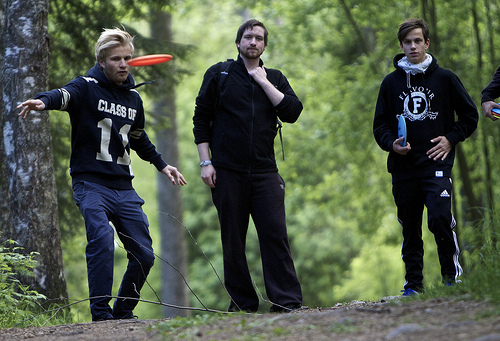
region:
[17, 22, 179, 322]
Just made frisbee airborn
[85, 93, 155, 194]
Navy shirt Class of 11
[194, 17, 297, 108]
Left hand holding collar open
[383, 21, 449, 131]
Dark blue Hoodie F bullseye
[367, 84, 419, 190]
Blue frisbee ready play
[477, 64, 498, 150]
Tip of another blue frisbee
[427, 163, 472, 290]
Pant leg white double stripe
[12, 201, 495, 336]
All standing sandy hill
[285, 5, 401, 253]
Forest behind frisbee players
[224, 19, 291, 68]
Only man facial hair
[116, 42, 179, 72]
An orange Frisbee in mid air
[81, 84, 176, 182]
Class of '11 sweat shirt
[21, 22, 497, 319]
Men playing frisbee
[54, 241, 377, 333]
A downed tree branch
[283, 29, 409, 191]
Greenery in the background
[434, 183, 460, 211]
An adidas logo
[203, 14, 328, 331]
An all black outfit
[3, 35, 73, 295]
A part of a tree trunk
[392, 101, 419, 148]
A blue frisbee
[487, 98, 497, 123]
Stack of different frisbees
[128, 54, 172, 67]
Orange frisbee in midair.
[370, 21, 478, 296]
Young man standing in forest.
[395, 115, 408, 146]
Bright blue frisbee in boy's hand.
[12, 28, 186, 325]
Young man tossing frisbee.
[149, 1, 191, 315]
Tall strong trunk of tree.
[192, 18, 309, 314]
Man with watch and backpack in forest.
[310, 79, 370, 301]
Section of green leafy tree.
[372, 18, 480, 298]
Young man waiting to toss frisbee.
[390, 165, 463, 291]
Men's Adidas sweat pants.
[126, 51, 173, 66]
Frisbee flying through the air.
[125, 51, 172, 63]
Orange frisbee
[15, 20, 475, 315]
Group of people playing frisbee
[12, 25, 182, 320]
Individual throwing the orange Frisbee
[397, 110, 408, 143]
Blue Frisbee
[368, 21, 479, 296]
Individual holding the blue frisbee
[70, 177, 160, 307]
Blue jeans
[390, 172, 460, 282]
Long sleeve Adidas pants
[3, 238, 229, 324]
Small tree branch that fell down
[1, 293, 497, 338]
Ground that contains dirt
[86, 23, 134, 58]
Blond hair on the individual throwing the frisbee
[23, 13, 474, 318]
young men playing frisbee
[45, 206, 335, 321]
branch across the path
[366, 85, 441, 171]
blue frisbee in a hand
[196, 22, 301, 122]
man pulling on neckline of jacket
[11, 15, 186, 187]
orange frisbee in front of man's head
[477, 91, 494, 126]
hand holding more than one frisbee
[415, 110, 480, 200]
hand resting on front of body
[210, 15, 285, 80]
man with facial hair with mouth closed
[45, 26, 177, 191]
man in shirt with graduation information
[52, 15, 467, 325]
men inside a wooded area